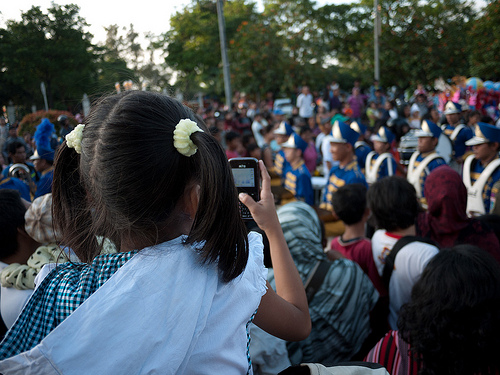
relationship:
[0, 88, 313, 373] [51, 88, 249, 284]
girl has hair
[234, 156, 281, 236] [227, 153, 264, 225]
girl's hand contains cell phone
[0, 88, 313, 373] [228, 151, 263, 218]
girl holding cell phone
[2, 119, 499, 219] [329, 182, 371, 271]
parade has person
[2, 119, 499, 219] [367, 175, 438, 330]
parade has people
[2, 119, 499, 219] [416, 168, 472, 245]
parade has person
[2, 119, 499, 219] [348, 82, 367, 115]
parade has person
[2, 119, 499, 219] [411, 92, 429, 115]
parade has person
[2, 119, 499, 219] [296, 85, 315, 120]
parade has person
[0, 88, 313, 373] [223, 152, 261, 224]
girl has phone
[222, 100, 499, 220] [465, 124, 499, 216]
band has uniform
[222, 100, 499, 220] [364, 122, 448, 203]
band has uniform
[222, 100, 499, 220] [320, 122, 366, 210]
band has uniform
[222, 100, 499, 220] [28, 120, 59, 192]
band has uniform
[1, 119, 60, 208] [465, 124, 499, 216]
band has uniform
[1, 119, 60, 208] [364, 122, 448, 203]
band has uniform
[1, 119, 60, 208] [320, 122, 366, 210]
band has uniform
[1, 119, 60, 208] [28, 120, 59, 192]
band has uniform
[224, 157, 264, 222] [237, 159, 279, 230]
phone held in girl's hand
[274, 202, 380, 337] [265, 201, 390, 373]
scarf worn by woman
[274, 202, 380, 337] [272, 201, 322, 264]
scarf worn on head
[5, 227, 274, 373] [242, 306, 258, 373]
fabric has end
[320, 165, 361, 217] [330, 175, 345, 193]
blue shirt has gold lines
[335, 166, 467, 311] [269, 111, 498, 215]
people watch band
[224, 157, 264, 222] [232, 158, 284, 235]
phone held in hand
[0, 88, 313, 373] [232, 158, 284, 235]
girl has hand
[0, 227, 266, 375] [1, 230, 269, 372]
fabric on shirt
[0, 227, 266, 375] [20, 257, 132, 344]
fabric on shirt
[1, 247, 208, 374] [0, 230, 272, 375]
hood on shirt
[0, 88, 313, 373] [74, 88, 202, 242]
girl has girls head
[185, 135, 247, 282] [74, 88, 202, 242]
pig tails on girls head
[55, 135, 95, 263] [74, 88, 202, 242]
pig tails on girls head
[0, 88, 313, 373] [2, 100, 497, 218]
girl watching a parade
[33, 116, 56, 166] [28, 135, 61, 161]
feather on a hat